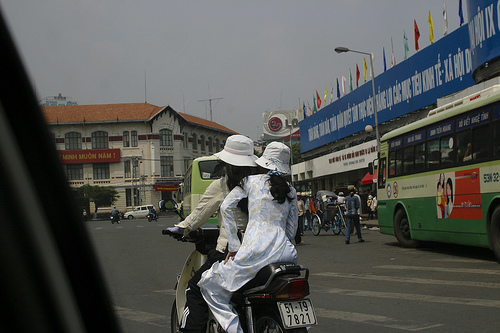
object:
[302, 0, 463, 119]
flags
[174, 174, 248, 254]
jacket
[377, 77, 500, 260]
bus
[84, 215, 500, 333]
road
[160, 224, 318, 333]
bike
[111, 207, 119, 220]
man motorcycle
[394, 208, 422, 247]
tire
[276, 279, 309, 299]
tail light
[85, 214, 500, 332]
ground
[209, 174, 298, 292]
dress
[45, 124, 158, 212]
wall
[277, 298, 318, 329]
plate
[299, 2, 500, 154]
blue sign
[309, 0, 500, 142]
white letters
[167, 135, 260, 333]
people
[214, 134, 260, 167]
hat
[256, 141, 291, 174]
hat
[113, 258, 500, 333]
crosswalk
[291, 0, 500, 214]
building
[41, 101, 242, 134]
roof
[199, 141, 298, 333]
people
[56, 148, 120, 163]
plaque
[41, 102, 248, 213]
building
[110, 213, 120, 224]
scooter